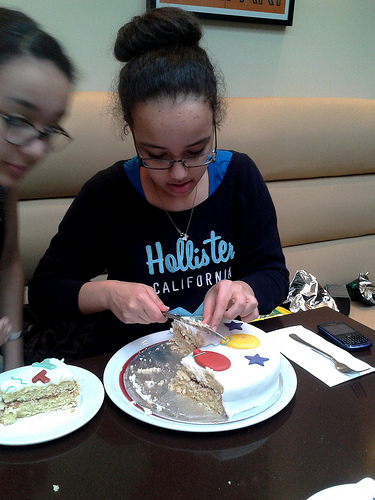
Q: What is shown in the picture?
A: A restaurant booth.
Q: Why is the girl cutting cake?
A: It's her birthday.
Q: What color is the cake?
A: White.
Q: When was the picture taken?
A: During a birthday party.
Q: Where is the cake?
A: On a table.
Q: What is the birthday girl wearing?
A: A sweatshirt.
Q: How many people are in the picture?
A: Two.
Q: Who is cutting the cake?
A: The girl.